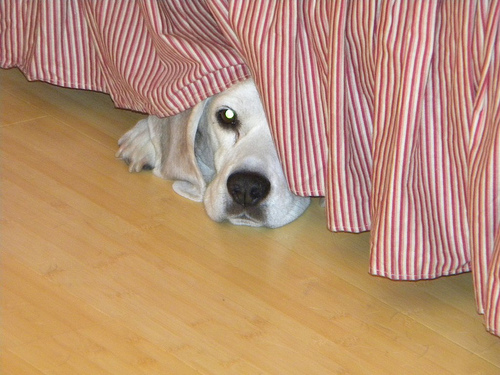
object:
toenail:
[127, 160, 134, 172]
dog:
[115, 76, 310, 227]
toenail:
[114, 140, 128, 157]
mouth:
[226, 204, 273, 233]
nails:
[132, 158, 146, 173]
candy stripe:
[391, 0, 423, 282]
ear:
[148, 101, 205, 203]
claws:
[115, 120, 155, 173]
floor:
[0, 63, 500, 375]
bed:
[0, 0, 499, 338]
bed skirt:
[0, 0, 499, 336]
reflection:
[223, 108, 233, 119]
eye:
[214, 106, 243, 127]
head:
[193, 79, 308, 229]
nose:
[223, 169, 270, 209]